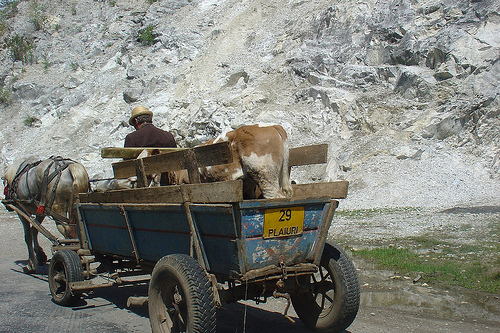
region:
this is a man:
[123, 100, 179, 156]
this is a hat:
[131, 105, 153, 121]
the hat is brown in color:
[133, 100, 152, 115]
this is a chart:
[76, 198, 312, 328]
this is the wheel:
[156, 267, 209, 323]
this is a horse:
[16, 155, 75, 215]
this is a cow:
[253, 117, 287, 191]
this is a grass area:
[436, 246, 470, 278]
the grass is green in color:
[375, 235, 415, 270]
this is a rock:
[333, 35, 479, 133]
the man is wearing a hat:
[129, 106, 154, 121]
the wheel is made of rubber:
[151, 250, 216, 330]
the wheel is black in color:
[149, 250, 218, 331]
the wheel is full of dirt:
[146, 255, 201, 332]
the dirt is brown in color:
[152, 262, 200, 331]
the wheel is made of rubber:
[49, 249, 83, 304]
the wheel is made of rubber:
[292, 240, 364, 331]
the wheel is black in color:
[51, 246, 84, 303]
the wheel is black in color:
[293, 240, 359, 331]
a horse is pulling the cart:
[8, 157, 91, 277]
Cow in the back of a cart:
[136, 120, 309, 201]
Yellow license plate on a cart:
[265, 204, 305, 236]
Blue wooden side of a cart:
[78, 202, 244, 272]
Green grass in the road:
[358, 242, 498, 298]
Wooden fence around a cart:
[111, 146, 248, 201]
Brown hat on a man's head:
[123, 105, 153, 120]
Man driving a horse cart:
[118, 108, 174, 184]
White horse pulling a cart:
[2, 156, 89, 271]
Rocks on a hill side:
[1, 3, 498, 205]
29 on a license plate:
[276, 210, 296, 222]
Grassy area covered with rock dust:
[299, 185, 499, 319]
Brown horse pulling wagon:
[2, 150, 88, 300]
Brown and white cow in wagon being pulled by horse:
[176, 119, 301, 209]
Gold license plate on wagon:
[252, 201, 311, 250]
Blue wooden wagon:
[72, 192, 343, 280]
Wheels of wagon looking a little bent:
[36, 235, 361, 330]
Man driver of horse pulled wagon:
[118, 101, 183, 194]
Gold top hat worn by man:
[125, 100, 157, 125]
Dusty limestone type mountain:
[13, 0, 483, 205]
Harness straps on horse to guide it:
[6, 155, 83, 223]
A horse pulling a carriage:
[4, 155, 90, 273]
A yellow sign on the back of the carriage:
[261, 205, 304, 237]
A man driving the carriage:
[97, 105, 177, 192]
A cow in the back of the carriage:
[149, 122, 289, 210]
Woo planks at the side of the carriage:
[79, 142, 243, 204]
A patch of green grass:
[352, 245, 499, 295]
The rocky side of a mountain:
[2, 1, 498, 207]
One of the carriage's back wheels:
[147, 253, 216, 331]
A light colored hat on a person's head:
[128, 105, 153, 123]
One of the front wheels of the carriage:
[48, 247, 83, 305]